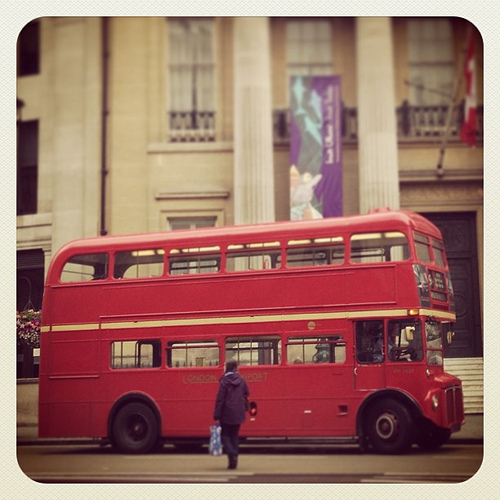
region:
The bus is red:
[102, 224, 427, 499]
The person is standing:
[194, 350, 294, 492]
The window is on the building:
[147, 48, 227, 153]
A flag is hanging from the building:
[251, 51, 396, 252]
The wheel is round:
[340, 373, 459, 490]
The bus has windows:
[76, 225, 438, 327]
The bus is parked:
[50, 153, 378, 458]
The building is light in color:
[57, 94, 147, 208]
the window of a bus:
[53, 242, 111, 282]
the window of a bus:
[111, 244, 167, 278]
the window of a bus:
[167, 245, 226, 275]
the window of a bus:
[224, 240, 287, 276]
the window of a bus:
[285, 235, 347, 270]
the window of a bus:
[345, 228, 410, 266]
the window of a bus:
[107, 335, 166, 372]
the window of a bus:
[163, 333, 225, 370]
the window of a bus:
[223, 333, 284, 369]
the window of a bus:
[286, 332, 347, 364]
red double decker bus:
[35, 204, 469, 469]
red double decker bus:
[26, 215, 450, 487]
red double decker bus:
[34, 188, 454, 466]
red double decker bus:
[29, 222, 474, 448]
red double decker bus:
[20, 211, 463, 458]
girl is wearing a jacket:
[203, 356, 257, 483]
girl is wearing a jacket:
[209, 356, 256, 439]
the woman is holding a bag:
[197, 343, 265, 491]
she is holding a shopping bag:
[190, 321, 293, 496]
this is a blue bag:
[202, 415, 227, 463]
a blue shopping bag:
[207, 419, 226, 457]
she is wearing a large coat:
[205, 361, 265, 433]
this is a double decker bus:
[25, 198, 474, 473]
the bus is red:
[32, 204, 484, 468]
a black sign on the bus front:
[422, 261, 458, 296]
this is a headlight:
[427, 388, 444, 417]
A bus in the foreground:
[27, 196, 472, 456]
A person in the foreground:
[195, 351, 260, 471]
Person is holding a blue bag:
[201, 347, 261, 472]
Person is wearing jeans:
[210, 421, 245, 466]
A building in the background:
[11, 15, 491, 411]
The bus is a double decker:
[18, 198, 469, 464]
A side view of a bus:
[28, 200, 468, 461]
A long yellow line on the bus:
[33, 302, 460, 344]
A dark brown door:
[393, 203, 487, 368]